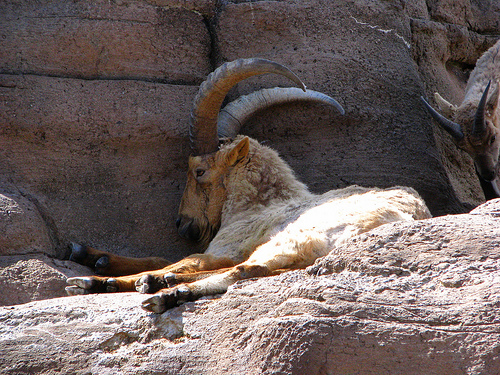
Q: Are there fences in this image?
A: No, there are no fences.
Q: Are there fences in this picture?
A: No, there are no fences.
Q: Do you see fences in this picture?
A: No, there are no fences.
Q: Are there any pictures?
A: No, there are no pictures.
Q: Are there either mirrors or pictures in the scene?
A: No, there are no pictures or mirrors.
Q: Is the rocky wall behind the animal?
A: Yes, the wall is behind the animal.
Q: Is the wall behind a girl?
A: No, the wall is behind the animal.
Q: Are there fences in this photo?
A: No, there are no fences.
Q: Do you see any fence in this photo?
A: No, there are no fences.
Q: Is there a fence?
A: No, there are no fences.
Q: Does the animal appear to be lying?
A: Yes, the animal is lying.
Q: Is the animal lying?
A: Yes, the animal is lying.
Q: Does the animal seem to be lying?
A: Yes, the animal is lying.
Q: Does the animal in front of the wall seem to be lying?
A: Yes, the animal is lying.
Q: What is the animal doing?
A: The animal is lying.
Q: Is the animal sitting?
A: No, the animal is lying.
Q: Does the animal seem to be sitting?
A: No, the animal is lying.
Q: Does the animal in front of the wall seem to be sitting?
A: No, the animal is lying.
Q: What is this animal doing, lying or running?
A: The animal is lying.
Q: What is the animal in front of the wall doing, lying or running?
A: The animal is lying.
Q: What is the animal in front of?
A: The animal is in front of the wall.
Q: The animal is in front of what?
A: The animal is in front of the wall.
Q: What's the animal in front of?
A: The animal is in front of the wall.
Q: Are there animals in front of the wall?
A: Yes, there is an animal in front of the wall.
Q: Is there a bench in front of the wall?
A: No, there is an animal in front of the wall.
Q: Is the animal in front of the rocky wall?
A: Yes, the animal is in front of the wall.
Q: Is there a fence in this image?
A: No, there are no fences.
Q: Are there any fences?
A: No, there are no fences.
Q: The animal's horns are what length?
A: The horns are short.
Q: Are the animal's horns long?
A: No, the horns are short.